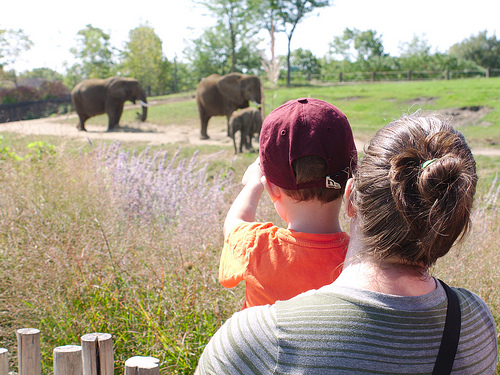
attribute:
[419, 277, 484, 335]
shoulder — mother's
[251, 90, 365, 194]
hat — maroon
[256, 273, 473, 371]
back — woman's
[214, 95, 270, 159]
elephant — baby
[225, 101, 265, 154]
elephant — baby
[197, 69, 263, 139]
elephant — adult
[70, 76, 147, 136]
elephant — adult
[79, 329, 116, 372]
fence post — wooden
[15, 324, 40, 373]
fence post — wooden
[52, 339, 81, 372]
fence post — wooden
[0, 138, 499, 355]
grass — tall, dry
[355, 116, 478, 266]
hair — brown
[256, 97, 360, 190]
hat — dark red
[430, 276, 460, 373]
strap — black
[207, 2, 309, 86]
all green trees — tall, in the distance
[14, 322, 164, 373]
small wooden poles — acting as fence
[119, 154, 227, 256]
grass is tall — dried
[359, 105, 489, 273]
ladies hair — tied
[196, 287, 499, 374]
striped shirt — gray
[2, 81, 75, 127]
wooden fence — in background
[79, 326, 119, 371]
wooden post — split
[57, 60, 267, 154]
three gray elephants — at zoo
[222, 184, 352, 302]
orange t-shirt — bright